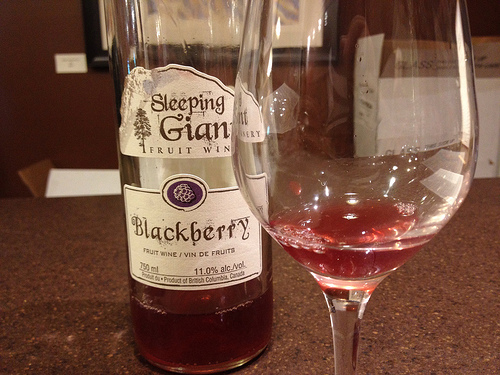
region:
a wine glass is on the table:
[225, 0, 484, 372]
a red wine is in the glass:
[251, 204, 442, 309]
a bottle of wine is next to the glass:
[109, 0, 279, 374]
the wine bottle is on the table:
[112, 0, 278, 372]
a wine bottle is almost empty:
[124, 252, 279, 374]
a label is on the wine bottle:
[114, 58, 274, 294]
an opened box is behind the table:
[356, 29, 498, 183]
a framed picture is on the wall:
[80, 5, 343, 71]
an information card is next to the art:
[51, 45, 91, 80]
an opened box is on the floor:
[17, 150, 124, 200]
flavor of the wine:
[113, 204, 260, 245]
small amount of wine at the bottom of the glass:
[272, 220, 401, 285]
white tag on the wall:
[48, 49, 90, 77]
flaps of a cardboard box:
[21, 141, 119, 197]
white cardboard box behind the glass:
[351, 33, 494, 163]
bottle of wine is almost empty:
[123, 275, 290, 372]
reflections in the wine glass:
[268, 64, 441, 196]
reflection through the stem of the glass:
[326, 287, 364, 314]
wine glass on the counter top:
[241, 24, 481, 374]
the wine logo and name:
[131, 87, 241, 156]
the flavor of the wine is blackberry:
[126, 205, 266, 255]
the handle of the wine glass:
[321, 307, 376, 374]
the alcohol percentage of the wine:
[191, 263, 250, 272]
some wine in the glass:
[247, 172, 457, 287]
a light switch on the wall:
[54, 48, 86, 78]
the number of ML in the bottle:
[136, 259, 163, 274]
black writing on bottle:
[107, 216, 255, 254]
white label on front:
[107, 52, 268, 296]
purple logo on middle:
[160, 179, 195, 207]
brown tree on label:
[130, 102, 152, 153]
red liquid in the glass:
[301, 198, 425, 286]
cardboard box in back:
[17, 155, 55, 199]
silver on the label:
[112, 156, 234, 187]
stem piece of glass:
[324, 292, 369, 370]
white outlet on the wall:
[57, 48, 85, 72]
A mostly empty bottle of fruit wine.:
[114, 1, 272, 370]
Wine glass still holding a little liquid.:
[232, 0, 473, 373]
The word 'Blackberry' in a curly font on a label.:
[130, 215, 256, 244]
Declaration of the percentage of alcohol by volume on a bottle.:
[189, 260, 248, 280]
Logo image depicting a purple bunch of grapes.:
[160, 174, 207, 211]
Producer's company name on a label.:
[150, 90, 240, 143]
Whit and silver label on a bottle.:
[119, 63, 264, 288]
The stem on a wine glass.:
[308, 269, 385, 374]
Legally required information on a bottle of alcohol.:
[136, 260, 248, 286]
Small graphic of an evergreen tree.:
[132, 108, 154, 155]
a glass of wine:
[219, 0, 486, 372]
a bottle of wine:
[106, 0, 292, 369]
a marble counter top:
[5, 167, 483, 374]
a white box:
[336, 23, 496, 210]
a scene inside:
[9, 13, 498, 351]